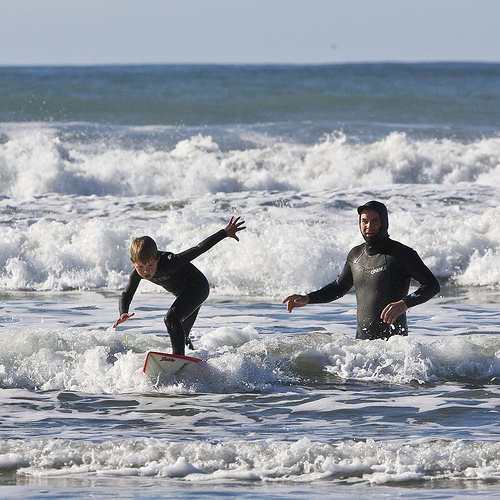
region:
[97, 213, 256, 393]
Boy learning to surf on surfboard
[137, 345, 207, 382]
Red and white surfboard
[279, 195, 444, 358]
Adult in water watching child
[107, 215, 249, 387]
Boy standing on surfboard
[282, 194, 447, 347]
Man in black wetsuit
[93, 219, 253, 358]
Boy in black wetsuit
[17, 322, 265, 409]
Small wave boy is surfing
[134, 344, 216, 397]
Surfboard coming out of water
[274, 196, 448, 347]
Man standing in ocean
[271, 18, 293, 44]
Small patch of the blue overcast sky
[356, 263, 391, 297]
Black wetsuit of the man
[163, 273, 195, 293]
Black wetsuit of the little boy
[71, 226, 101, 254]
White waves in the ocean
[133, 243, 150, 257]
Brown hair of the little boy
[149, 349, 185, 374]
Red and white back of the surfboard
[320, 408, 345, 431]
Small patch of the blue and white ocean water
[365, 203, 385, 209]
Black hat of the man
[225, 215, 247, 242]
Left hand of the boy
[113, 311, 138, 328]
Right hand of the boy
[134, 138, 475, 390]
people in the water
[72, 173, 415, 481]
a body of water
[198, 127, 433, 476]
a body of blue water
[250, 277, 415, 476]
a body of water that is wavy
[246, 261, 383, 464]
a body of blue water that is wavy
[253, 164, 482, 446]
a body of blue water with waves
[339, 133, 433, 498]
a man standing in the water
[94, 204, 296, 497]
a boy riding a surfboard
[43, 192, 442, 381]
man and boy are in the water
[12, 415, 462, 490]
the waves are white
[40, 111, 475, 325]
the waves are rolling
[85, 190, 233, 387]
boy is standing on the surfboard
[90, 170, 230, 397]
the boy is surfing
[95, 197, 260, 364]
the boy is wearing a wet suit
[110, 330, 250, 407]
the surfboard is white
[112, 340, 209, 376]
the surfboard edge is red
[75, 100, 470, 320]
the waves are splashing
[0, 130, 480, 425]
the waves are in motion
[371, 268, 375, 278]
white letter on wetsuit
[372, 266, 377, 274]
white letter on wetsuit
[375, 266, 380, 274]
white letter on wetsuit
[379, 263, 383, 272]
white letter on wetsuit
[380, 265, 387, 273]
white letter on wetsuit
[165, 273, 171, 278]
white letter on wetsuit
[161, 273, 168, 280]
white letter on wetsuit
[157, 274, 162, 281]
white letter on wetsuit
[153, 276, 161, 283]
white letter on wetsuit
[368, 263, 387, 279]
white letters on wetsuit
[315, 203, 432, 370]
man standing in the water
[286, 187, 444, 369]
man wearing a black wet suit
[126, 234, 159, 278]
boy with blonde hair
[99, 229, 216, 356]
boy wearing a black wet suit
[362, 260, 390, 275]
man with logo on wetsuit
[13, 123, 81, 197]
waves crashing in the ocean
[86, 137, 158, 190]
waves crashing in the ocean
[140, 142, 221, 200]
waves crashing in the ocean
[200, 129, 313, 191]
waves crashing in the ocean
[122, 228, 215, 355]
a boy surfin gin the water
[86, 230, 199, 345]
a boy wearing a wetsuit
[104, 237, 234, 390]
a boy on a surfboard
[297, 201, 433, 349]
a boy in the water